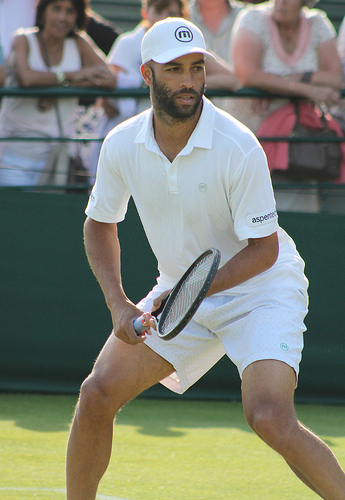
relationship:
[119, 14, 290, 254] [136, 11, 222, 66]
man wearing hat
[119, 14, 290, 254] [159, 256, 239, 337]
man holding racket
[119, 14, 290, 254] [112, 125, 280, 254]
man wearing shirt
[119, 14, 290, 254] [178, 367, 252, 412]
man wearing shorts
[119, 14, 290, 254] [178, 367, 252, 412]
man in shorts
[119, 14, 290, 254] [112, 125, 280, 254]
man in shirt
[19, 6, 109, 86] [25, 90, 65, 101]
woman on rail